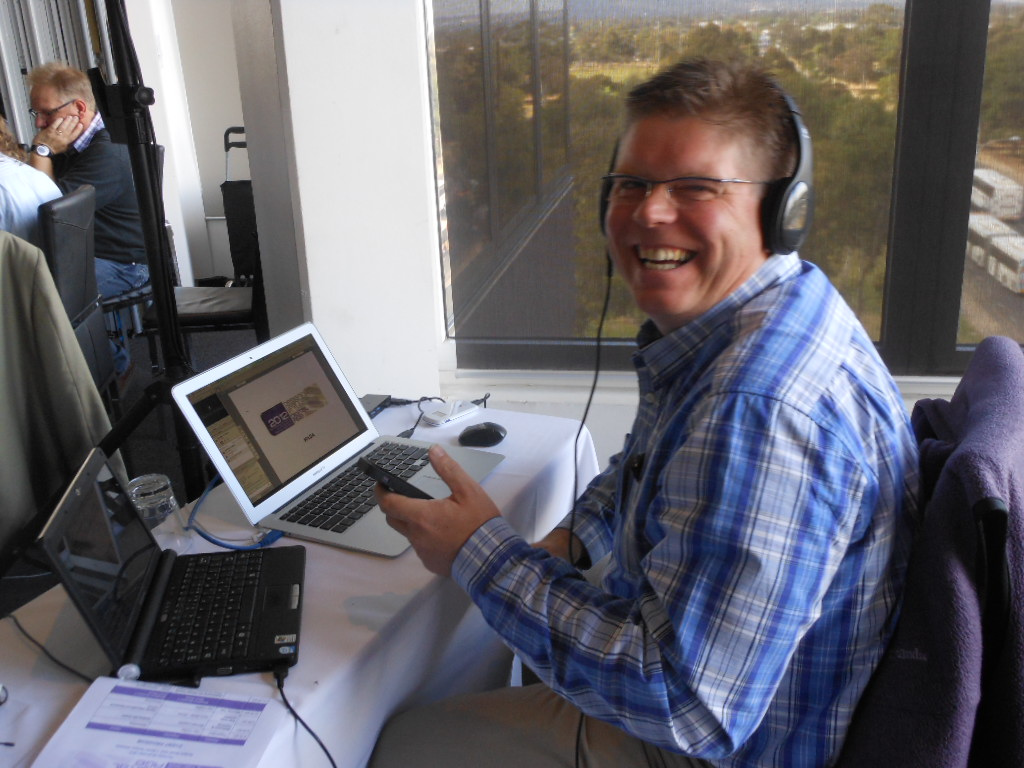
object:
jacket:
[837, 336, 1024, 768]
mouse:
[458, 422, 507, 447]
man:
[24, 61, 152, 397]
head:
[25, 61, 97, 146]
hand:
[33, 116, 83, 155]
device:
[358, 456, 437, 500]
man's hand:
[375, 444, 504, 578]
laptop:
[169, 321, 505, 561]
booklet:
[33, 676, 274, 767]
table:
[0, 395, 600, 768]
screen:
[54, 461, 158, 665]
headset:
[600, 61, 810, 255]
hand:
[375, 445, 503, 577]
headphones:
[600, 56, 814, 338]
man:
[354, 56, 920, 768]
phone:
[354, 457, 433, 500]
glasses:
[600, 173, 770, 201]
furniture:
[0, 392, 1024, 764]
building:
[0, 0, 1024, 768]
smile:
[632, 245, 700, 279]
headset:
[763, 78, 813, 255]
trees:
[433, 4, 1024, 345]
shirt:
[451, 249, 920, 768]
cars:
[963, 168, 1024, 293]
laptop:
[33, 447, 306, 681]